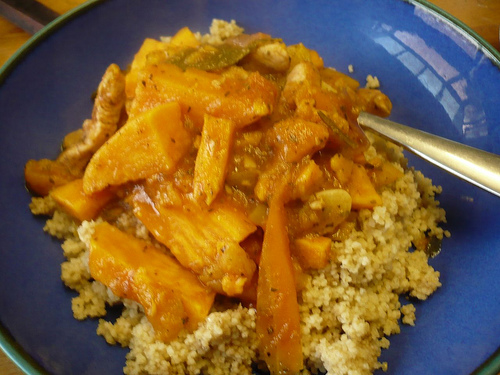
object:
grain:
[327, 228, 440, 373]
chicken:
[24, 23, 390, 375]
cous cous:
[27, 15, 435, 373]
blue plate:
[1, 0, 500, 375]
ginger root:
[57, 63, 124, 167]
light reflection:
[373, 11, 490, 142]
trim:
[393, 4, 497, 74]